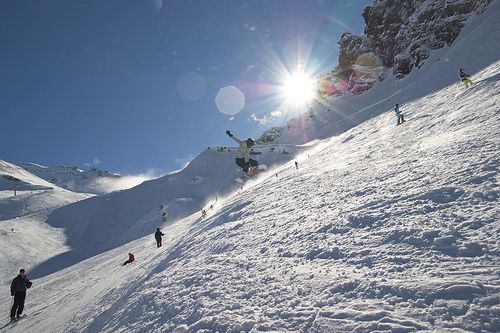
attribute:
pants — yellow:
[462, 79, 473, 90]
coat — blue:
[394, 108, 404, 117]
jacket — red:
[128, 252, 137, 263]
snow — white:
[0, 158, 498, 332]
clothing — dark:
[153, 231, 165, 249]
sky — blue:
[1, 1, 376, 177]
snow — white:
[402, 9, 421, 22]